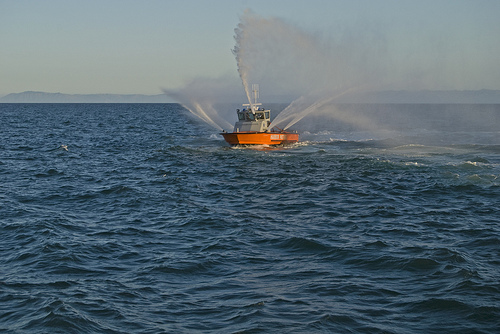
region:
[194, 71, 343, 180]
the boat is shooting water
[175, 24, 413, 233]
the boat is spraying water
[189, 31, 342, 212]
the boat is on the water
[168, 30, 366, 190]
the boat is in the ocean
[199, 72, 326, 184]
the boat is orange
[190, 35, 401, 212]
the boat is white and orange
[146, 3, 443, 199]
there is a lot of water spray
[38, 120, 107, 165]
a pelican flying above the water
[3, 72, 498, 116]
an island in the distance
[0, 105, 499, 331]
there are a lot of small waves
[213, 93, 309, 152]
boat in the water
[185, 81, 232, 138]
spout of water coming out of boat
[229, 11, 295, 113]
spout of water coming out of boat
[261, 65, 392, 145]
spout of water coming out of boat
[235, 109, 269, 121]
windows on the boat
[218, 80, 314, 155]
orange and white boat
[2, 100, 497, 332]
water is blue and choppy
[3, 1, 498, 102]
sky is blue and hazy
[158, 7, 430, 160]
boat spraying out water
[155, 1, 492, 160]
orange and white boat spraying water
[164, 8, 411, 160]
a large boat spraying water on the sides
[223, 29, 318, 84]
water being sprayed out of the boat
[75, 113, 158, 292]
lots of clear deep blue ocean water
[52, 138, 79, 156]
a small bird flying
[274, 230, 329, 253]
an ocean wave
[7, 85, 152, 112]
some mountains in the distance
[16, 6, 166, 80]
a clear sky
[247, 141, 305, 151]
some foamy waters created from the boat moving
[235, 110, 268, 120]
some windows on the boat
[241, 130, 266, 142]
the color orange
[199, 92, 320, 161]
A boat on the water.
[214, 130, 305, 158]
The bottom is white.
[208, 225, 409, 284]
The water is blue.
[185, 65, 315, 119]
The water is white.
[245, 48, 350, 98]
Water in the air.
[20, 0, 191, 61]
The sky is blue.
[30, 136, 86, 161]
Bird in the water.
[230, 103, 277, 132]
Top of the boat is white.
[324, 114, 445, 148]
Water is light blue.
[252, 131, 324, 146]
Writing on the side of the boat.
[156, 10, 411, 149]
rescue fire boat on the water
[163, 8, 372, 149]
rescue fire boat blowing water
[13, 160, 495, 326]
choppy blue ocean water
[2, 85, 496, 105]
mountains separate the water and the sky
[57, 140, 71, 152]
seagull flying near the water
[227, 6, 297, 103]
water shooting straight up from the boat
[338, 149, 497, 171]
small white caps on the water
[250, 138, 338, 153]
wake of moving boat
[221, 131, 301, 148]
orange hull of boat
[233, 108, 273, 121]
windshield and side windows on boat